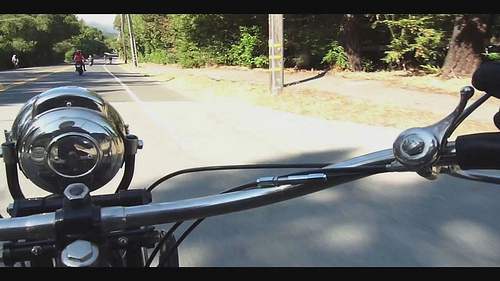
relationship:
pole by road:
[269, 13, 289, 93] [5, 57, 495, 277]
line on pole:
[264, 58, 281, 75] [268, 14, 284, 98]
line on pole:
[268, 38, 286, 55] [268, 14, 284, 98]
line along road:
[102, 61, 142, 112] [4, 66, 185, 133]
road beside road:
[0, 57, 496, 277] [13, 64, 148, 101]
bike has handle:
[1, 54, 498, 266] [454, 128, 499, 171]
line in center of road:
[102, 61, 142, 112] [49, 57, 134, 97]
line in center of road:
[0, 66, 77, 100] [49, 57, 134, 97]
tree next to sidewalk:
[324, 8, 498, 83] [122, 52, 497, 140]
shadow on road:
[132, 147, 499, 265] [5, 57, 495, 277]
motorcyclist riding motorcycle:
[73, 50, 87, 73] [71, 57, 92, 75]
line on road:
[109, 61, 141, 113] [17, 40, 162, 150]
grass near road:
[289, 92, 412, 128] [3, 59, 243, 234]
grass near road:
[172, 72, 256, 100] [3, 59, 243, 234]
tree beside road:
[4, 19, 39, 55] [135, 83, 201, 144]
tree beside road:
[130, 8, 185, 61] [135, 83, 201, 144]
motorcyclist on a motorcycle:
[73, 50, 87, 73] [69, 62, 89, 74]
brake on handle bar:
[395, 85, 472, 167] [2, 95, 497, 252]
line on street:
[268, 38, 286, 55] [2, 60, 131, 103]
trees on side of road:
[114, 12, 496, 70] [4, 50, 266, 158]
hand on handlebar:
[472, 44, 497, 104] [6, 122, 494, 264]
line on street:
[102, 61, 142, 112] [2, 56, 202, 196]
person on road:
[7, 48, 24, 70] [0, 57, 496, 277]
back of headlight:
[16, 112, 127, 193] [2, 81, 142, 202]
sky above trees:
[77, 14, 125, 27] [0, 14, 500, 86]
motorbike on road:
[68, 50, 89, 80] [6, 65, 497, 243]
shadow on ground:
[132, 147, 499, 265] [0, 59, 497, 269]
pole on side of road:
[264, 13, 289, 95] [5, 57, 495, 277]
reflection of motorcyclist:
[21, 113, 138, 205] [25, 117, 98, 178]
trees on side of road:
[114, 12, 496, 70] [2, 63, 267, 278]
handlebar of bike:
[6, 130, 498, 237] [1, 54, 498, 266]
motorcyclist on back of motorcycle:
[73, 50, 87, 73] [72, 56, 87, 76]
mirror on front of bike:
[10, 107, 132, 181] [1, 54, 498, 266]